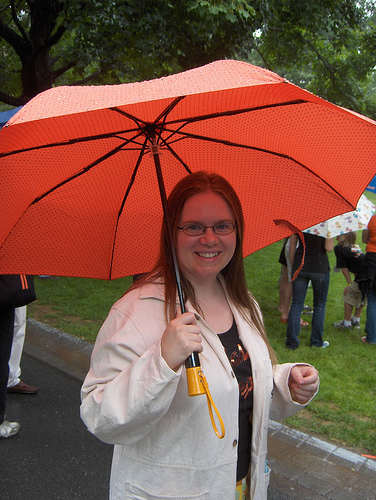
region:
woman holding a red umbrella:
[5, 41, 367, 455]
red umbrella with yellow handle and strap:
[29, 54, 266, 409]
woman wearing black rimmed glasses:
[144, 160, 280, 302]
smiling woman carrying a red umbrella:
[102, 56, 283, 404]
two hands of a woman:
[140, 308, 339, 403]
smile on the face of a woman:
[185, 242, 244, 271]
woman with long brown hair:
[157, 163, 253, 345]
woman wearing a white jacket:
[70, 134, 288, 471]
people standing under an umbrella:
[265, 185, 372, 360]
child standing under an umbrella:
[321, 196, 369, 341]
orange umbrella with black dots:
[0, 53, 374, 317]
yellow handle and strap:
[176, 359, 237, 447]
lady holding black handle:
[122, 131, 212, 447]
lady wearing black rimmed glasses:
[169, 206, 285, 258]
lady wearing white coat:
[85, 126, 316, 493]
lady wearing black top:
[200, 321, 286, 493]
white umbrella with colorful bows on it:
[305, 194, 375, 242]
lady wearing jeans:
[285, 257, 373, 354]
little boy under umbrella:
[322, 228, 374, 334]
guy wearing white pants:
[0, 155, 46, 436]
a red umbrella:
[1, 44, 371, 293]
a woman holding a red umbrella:
[1, 8, 370, 431]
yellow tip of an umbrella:
[182, 360, 236, 443]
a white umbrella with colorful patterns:
[305, 196, 374, 237]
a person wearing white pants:
[9, 306, 31, 391]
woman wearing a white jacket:
[95, 276, 315, 496]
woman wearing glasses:
[174, 213, 242, 238]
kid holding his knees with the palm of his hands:
[330, 232, 369, 338]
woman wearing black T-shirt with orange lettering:
[214, 315, 264, 475]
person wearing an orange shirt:
[367, 213, 375, 253]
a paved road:
[3, 439, 95, 492]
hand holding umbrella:
[144, 294, 227, 442]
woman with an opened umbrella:
[109, 171, 273, 320]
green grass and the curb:
[36, 279, 74, 370]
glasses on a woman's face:
[169, 207, 240, 233]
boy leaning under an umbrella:
[330, 216, 363, 332]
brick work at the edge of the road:
[278, 431, 372, 488]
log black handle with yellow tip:
[144, 151, 204, 403]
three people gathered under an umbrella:
[279, 200, 359, 339]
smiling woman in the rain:
[51, 89, 350, 429]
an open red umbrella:
[2, 60, 373, 279]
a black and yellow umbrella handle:
[181, 343, 225, 444]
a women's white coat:
[77, 272, 319, 493]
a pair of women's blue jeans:
[285, 266, 324, 348]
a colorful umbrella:
[297, 192, 374, 236]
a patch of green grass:
[29, 239, 374, 453]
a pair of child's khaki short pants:
[342, 280, 366, 306]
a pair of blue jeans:
[358, 253, 374, 336]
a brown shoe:
[9, 380, 38, 396]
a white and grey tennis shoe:
[0, 419, 23, 438]